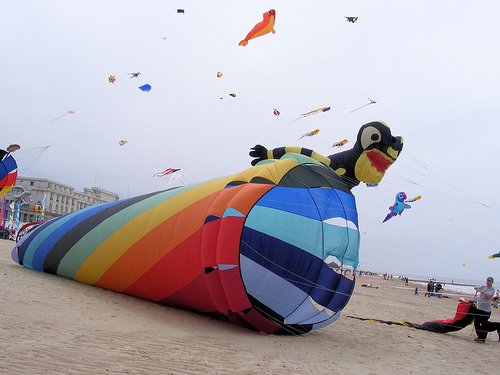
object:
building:
[0, 176, 120, 235]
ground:
[411, 174, 437, 199]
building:
[239, 8, 276, 46]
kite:
[238, 9, 277, 46]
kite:
[248, 120, 405, 192]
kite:
[298, 129, 319, 140]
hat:
[486, 277, 494, 286]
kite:
[381, 191, 421, 223]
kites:
[289, 106, 330, 125]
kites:
[350, 97, 378, 113]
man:
[473, 276, 499, 344]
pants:
[472, 307, 500, 345]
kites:
[49, 7, 378, 126]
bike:
[473, 276, 495, 343]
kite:
[138, 83, 151, 92]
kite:
[343, 300, 477, 335]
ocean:
[380, 274, 499, 303]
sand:
[0, 215, 499, 375]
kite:
[11, 121, 403, 338]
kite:
[296, 106, 332, 120]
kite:
[107, 74, 116, 83]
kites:
[108, 71, 152, 92]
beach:
[0, 216, 499, 374]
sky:
[0, 0, 498, 305]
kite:
[108, 74, 116, 83]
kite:
[118, 139, 127, 146]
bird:
[382, 191, 422, 223]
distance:
[16, 147, 67, 216]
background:
[352, 268, 500, 313]